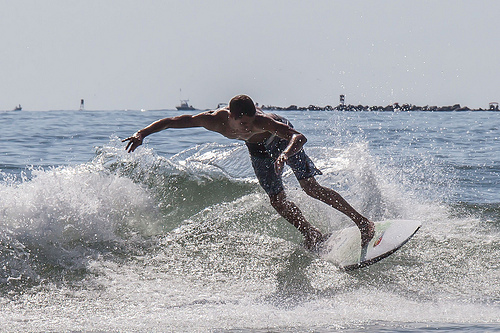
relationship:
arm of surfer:
[131, 108, 174, 145] [178, 24, 362, 229]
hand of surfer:
[115, 127, 145, 155] [178, 24, 362, 229]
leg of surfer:
[274, 202, 322, 251] [178, 24, 362, 229]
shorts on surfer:
[235, 146, 310, 185] [178, 24, 362, 229]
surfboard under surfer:
[289, 214, 425, 272] [178, 24, 362, 229]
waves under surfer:
[102, 167, 292, 293] [178, 24, 362, 229]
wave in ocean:
[27, 176, 171, 269] [35, 109, 208, 289]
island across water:
[267, 68, 492, 135] [290, 63, 500, 175]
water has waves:
[290, 63, 500, 175] [102, 167, 292, 293]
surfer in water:
[178, 24, 362, 229] [290, 63, 500, 175]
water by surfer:
[290, 63, 500, 175] [178, 24, 362, 229]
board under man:
[323, 206, 441, 280] [155, 91, 391, 232]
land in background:
[298, 88, 465, 128] [52, 34, 487, 141]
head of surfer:
[209, 85, 279, 134] [178, 24, 362, 229]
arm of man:
[131, 108, 174, 145] [155, 91, 391, 232]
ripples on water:
[40, 120, 107, 157] [290, 63, 500, 175]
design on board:
[374, 232, 400, 248] [323, 206, 441, 280]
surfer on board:
[178, 24, 362, 229] [323, 206, 441, 280]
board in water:
[323, 206, 441, 280] [290, 63, 500, 175]